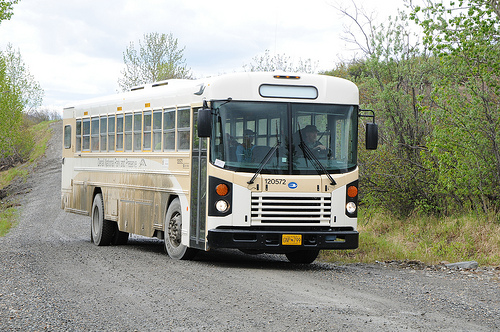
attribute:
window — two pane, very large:
[201, 87, 372, 188]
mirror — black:
[199, 98, 213, 138]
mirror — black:
[359, 108, 377, 143]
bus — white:
[61, 69, 379, 269]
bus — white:
[61, 73, 359, 260]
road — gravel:
[0, 119, 498, 330]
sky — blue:
[188, 14, 242, 54]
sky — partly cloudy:
[38, 37, 84, 64]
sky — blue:
[48, 16, 101, 80]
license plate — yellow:
[273, 222, 317, 256]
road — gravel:
[13, 218, 498, 330]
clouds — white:
[114, 10, 186, 32]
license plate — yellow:
[277, 230, 302, 245]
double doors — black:
[175, 117, 215, 224]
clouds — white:
[1, 8, 497, 121]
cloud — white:
[226, 6, 335, 38]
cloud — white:
[42, 42, 99, 91]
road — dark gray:
[4, 241, 496, 330]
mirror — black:
[358, 105, 382, 148]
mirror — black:
[195, 107, 215, 137]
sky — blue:
[178, 43, 243, 75]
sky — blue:
[187, 43, 250, 74]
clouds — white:
[186, 7, 314, 50]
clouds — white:
[282, 17, 309, 56]